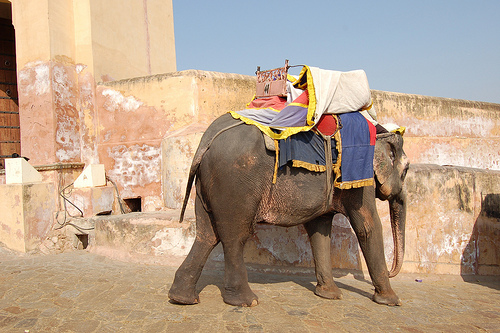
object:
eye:
[398, 167, 408, 182]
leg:
[218, 225, 253, 291]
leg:
[170, 195, 220, 287]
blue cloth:
[351, 138, 365, 167]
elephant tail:
[181, 148, 207, 224]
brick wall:
[368, 161, 500, 275]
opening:
[117, 197, 144, 214]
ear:
[368, 133, 405, 208]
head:
[373, 127, 413, 279]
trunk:
[386, 191, 406, 278]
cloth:
[337, 77, 367, 97]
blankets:
[325, 111, 377, 190]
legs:
[301, 212, 333, 285]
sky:
[172, 0, 499, 106]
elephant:
[167, 104, 412, 306]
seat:
[255, 56, 372, 115]